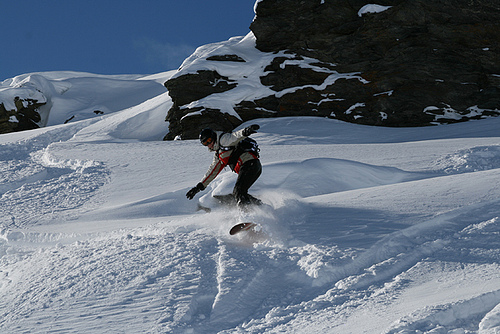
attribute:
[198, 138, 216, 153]
goggles — oranges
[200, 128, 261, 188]
jacket — tan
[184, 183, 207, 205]
hand — gloved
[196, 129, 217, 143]
helmet — black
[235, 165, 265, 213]
pants — black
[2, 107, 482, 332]
slope — snowy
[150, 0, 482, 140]
cliff — rocky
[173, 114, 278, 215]
skier — going down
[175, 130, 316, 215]
arms — extended